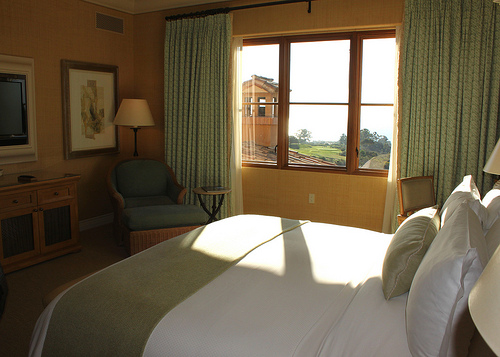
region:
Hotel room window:
[236, 38, 397, 171]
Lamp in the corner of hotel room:
[115, 94, 155, 156]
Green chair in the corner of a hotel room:
[106, 150, 192, 207]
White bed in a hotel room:
[33, 213, 463, 353]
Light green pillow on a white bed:
[381, 205, 438, 300]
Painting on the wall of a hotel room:
[61, 56, 123, 157]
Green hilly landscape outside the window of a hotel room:
[289, 105, 395, 158]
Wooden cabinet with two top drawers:
[4, 165, 86, 259]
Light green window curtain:
[159, 13, 236, 214]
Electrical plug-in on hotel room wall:
[306, 190, 318, 205]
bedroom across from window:
[2, 4, 496, 340]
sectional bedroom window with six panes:
[228, 37, 394, 169]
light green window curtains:
[402, 4, 498, 186]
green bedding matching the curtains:
[206, 215, 431, 295]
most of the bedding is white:
[301, 219, 471, 353]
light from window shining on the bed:
[191, 196, 428, 296]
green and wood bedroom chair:
[89, 145, 220, 247]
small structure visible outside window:
[238, 66, 288, 166]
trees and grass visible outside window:
[289, 119, 390, 168]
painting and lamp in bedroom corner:
[52, 47, 164, 154]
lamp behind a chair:
[113, 94, 152, 156]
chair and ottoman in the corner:
[105, 152, 206, 243]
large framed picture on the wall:
[55, 55, 120, 160]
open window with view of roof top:
[235, 23, 406, 177]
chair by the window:
[397, 175, 432, 218]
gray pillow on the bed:
[381, 200, 435, 308]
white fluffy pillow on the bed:
[405, 174, 486, 350]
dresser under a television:
[1, 173, 81, 269]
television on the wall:
[0, 54, 39, 164]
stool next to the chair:
[192, 184, 227, 215]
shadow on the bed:
[266, 224, 338, 297]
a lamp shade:
[118, 97, 151, 124]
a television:
[4, 83, 33, 151]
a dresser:
[6, 182, 79, 206]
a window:
[293, 49, 396, 164]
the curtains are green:
[398, 19, 493, 147]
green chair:
[107, 160, 185, 202]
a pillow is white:
[405, 285, 449, 340]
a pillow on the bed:
[382, 213, 420, 283]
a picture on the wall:
[58, 60, 115, 156]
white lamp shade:
[112, 95, 155, 127]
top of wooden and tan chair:
[398, 172, 438, 215]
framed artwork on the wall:
[59, 59, 120, 154]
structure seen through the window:
[241, 75, 280, 161]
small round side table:
[196, 182, 229, 222]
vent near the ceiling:
[95, 10, 122, 34]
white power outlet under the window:
[307, 193, 315, 204]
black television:
[1, 75, 29, 142]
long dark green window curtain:
[163, 14, 230, 218]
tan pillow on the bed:
[381, 200, 439, 297]